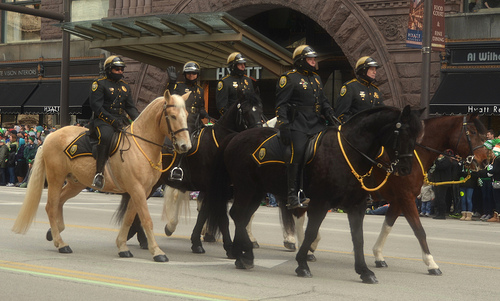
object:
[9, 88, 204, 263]
horse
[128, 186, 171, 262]
leg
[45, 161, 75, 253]
leg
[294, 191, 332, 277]
leg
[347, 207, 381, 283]
leg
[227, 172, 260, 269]
leg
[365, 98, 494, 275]
horse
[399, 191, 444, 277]
leg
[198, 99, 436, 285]
horse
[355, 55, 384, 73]
helmet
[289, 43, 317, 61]
helmet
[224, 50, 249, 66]
helmet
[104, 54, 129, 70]
helmet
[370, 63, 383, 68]
visor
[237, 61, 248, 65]
visor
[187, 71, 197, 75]
visor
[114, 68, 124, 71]
visor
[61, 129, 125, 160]
saddle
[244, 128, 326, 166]
saddle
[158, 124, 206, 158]
saddle